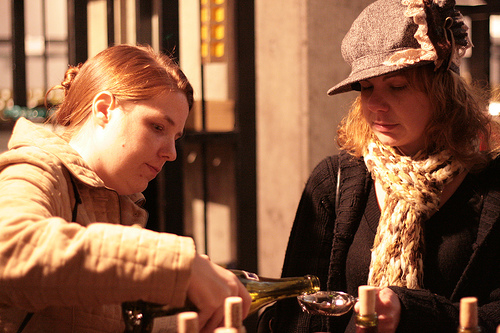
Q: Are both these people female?
A: Yes, all the people are female.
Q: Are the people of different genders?
A: No, all the people are female.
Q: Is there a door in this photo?
A: Yes, there are doors.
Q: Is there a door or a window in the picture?
A: Yes, there are doors.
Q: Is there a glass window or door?
A: Yes, there are glass doors.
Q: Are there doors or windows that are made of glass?
A: Yes, the doors are made of glass.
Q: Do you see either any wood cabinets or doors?
A: Yes, there are wood doors.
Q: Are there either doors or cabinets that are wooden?
A: Yes, the doors are wooden.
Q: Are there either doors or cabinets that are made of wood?
A: Yes, the doors are made of wood.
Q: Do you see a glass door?
A: Yes, there are doors that are made of glass.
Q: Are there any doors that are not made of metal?
A: Yes, there are doors that are made of glass.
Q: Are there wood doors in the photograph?
A: Yes, there are wood doors.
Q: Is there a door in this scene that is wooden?
A: Yes, there are doors that are wooden.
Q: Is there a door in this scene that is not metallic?
A: Yes, there are wooden doors.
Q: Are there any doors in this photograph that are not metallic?
A: Yes, there are wooden doors.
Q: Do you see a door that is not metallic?
A: Yes, there are wooden doors.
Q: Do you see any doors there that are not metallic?
A: Yes, there are wooden doors.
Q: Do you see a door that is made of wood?
A: Yes, there are doors that are made of wood.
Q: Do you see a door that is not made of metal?
A: Yes, there are doors that are made of wood.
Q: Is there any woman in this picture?
A: Yes, there is a woman.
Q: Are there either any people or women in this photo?
A: Yes, there is a woman.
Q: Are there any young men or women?
A: Yes, there is a young woman.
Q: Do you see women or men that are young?
A: Yes, the woman is young.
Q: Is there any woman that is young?
A: Yes, there is a young woman.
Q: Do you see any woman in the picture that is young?
A: Yes, there is a woman that is young.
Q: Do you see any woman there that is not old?
A: Yes, there is an young woman.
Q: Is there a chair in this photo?
A: No, there are no chairs.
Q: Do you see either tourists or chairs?
A: No, there are no chairs or tourists.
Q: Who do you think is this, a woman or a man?
A: This is a woman.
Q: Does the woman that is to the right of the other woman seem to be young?
A: Yes, the woman is young.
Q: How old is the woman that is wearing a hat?
A: The woman is young.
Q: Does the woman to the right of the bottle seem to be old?
A: No, the woman is young.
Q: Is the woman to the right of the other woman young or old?
A: The woman is young.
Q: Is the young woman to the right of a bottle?
A: Yes, the woman is to the right of a bottle.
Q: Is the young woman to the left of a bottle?
A: No, the woman is to the right of a bottle.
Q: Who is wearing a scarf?
A: The woman is wearing a scarf.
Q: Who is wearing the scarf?
A: The woman is wearing a scarf.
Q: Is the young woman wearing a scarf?
A: Yes, the woman is wearing a scarf.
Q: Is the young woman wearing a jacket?
A: No, the woman is wearing a scarf.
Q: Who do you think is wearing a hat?
A: The woman is wearing a hat.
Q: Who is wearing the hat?
A: The woman is wearing a hat.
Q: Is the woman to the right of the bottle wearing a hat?
A: Yes, the woman is wearing a hat.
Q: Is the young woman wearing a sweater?
A: No, the woman is wearing a hat.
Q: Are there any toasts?
A: No, there are no toasts.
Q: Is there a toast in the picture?
A: No, there are no toasts.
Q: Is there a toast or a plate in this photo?
A: No, there are no toasts or plates.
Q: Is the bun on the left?
A: Yes, the bun is on the left of the image.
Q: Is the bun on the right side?
A: No, the bun is on the left of the image.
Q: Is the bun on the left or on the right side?
A: The bun is on the left of the image.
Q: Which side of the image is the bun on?
A: The bun is on the left of the image.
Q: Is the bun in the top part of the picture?
A: Yes, the bun is in the top of the image.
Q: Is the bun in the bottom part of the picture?
A: No, the bun is in the top of the image.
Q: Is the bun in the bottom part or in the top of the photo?
A: The bun is in the top of the image.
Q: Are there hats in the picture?
A: Yes, there is a hat.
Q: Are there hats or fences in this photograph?
A: Yes, there is a hat.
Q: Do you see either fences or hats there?
A: Yes, there is a hat.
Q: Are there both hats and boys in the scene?
A: No, there is a hat but no boys.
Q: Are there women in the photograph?
A: Yes, there is a woman.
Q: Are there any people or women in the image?
A: Yes, there is a woman.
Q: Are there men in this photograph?
A: No, there are no men.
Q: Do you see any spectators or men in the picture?
A: No, there are no men or spectators.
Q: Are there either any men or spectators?
A: No, there are no men or spectators.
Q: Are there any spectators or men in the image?
A: No, there are no men or spectators.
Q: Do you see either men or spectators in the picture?
A: No, there are no men or spectators.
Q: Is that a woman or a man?
A: That is a woman.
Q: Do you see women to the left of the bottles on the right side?
A: Yes, there is a woman to the left of the bottles.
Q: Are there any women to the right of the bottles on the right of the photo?
A: No, the woman is to the left of the bottles.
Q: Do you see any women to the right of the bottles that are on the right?
A: No, the woman is to the left of the bottles.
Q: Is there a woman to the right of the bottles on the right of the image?
A: No, the woman is to the left of the bottles.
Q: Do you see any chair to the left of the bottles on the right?
A: No, there is a woman to the left of the bottles.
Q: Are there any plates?
A: No, there are no plates.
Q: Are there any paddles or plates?
A: No, there are no plates or paddles.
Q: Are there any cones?
A: No, there are no cones.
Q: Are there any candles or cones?
A: No, there are no cones or candles.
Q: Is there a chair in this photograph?
A: No, there are no chairs.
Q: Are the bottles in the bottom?
A: Yes, the bottles are in the bottom of the image.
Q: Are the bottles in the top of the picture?
A: No, the bottles are in the bottom of the image.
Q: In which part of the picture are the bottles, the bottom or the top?
A: The bottles are in the bottom of the image.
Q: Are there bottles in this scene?
A: Yes, there is a bottle.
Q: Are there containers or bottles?
A: Yes, there is a bottle.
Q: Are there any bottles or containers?
A: Yes, there is a bottle.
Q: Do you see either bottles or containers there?
A: Yes, there is a bottle.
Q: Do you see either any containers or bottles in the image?
A: Yes, there is a bottle.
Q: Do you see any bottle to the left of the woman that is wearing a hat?
A: Yes, there is a bottle to the left of the woman.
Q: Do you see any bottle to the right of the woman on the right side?
A: No, the bottle is to the left of the woman.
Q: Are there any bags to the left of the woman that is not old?
A: No, there is a bottle to the left of the woman.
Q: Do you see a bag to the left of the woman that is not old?
A: No, there is a bottle to the left of the woman.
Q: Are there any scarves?
A: Yes, there is a scarf.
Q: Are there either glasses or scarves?
A: Yes, there is a scarf.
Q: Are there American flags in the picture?
A: No, there are no American flags.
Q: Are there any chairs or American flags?
A: No, there are no American flags or chairs.